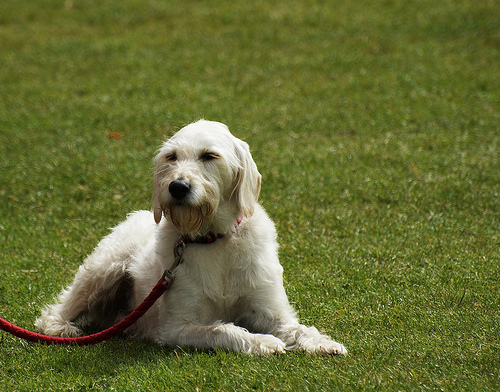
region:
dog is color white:
[22, 105, 349, 367]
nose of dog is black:
[164, 172, 191, 204]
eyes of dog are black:
[160, 144, 221, 165]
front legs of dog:
[172, 305, 357, 369]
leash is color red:
[1, 227, 202, 355]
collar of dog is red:
[161, 216, 251, 250]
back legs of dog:
[31, 257, 123, 342]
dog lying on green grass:
[28, 103, 353, 380]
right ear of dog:
[228, 135, 270, 222]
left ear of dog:
[148, 152, 168, 225]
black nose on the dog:
[167, 180, 191, 200]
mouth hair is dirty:
[162, 204, 209, 227]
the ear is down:
[233, 144, 259, 214]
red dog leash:
[0, 278, 171, 345]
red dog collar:
[185, 213, 244, 245]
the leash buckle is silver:
[161, 238, 185, 279]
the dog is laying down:
[37, 117, 347, 357]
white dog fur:
[108, 219, 153, 266]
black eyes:
[160, 151, 217, 160]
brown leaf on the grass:
[107, 131, 119, 138]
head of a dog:
[124, 83, 275, 247]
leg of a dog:
[152, 308, 263, 373]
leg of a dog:
[249, 295, 330, 351]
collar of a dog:
[157, 205, 254, 268]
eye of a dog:
[163, 141, 187, 175]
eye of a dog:
[189, 131, 230, 173]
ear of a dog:
[141, 175, 191, 231]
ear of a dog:
[230, 129, 292, 216]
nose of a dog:
[166, 171, 200, 192]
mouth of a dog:
[152, 198, 224, 229]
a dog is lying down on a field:
[23, 101, 373, 380]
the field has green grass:
[6, 9, 491, 386]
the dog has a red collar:
[167, 209, 251, 249]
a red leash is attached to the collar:
[1, 238, 199, 356]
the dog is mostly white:
[33, 116, 348, 359]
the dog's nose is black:
[166, 177, 193, 201]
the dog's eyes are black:
[155, 150, 226, 161]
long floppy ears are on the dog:
[141, 131, 266, 231]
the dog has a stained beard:
[152, 198, 220, 237]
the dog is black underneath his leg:
[53, 261, 194, 358]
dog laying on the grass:
[23, 111, 362, 375]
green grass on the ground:
[1, 0, 499, 388]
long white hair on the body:
[32, 112, 352, 367]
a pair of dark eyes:
[159, 145, 226, 165]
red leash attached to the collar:
[0, 237, 201, 342]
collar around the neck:
[173, 208, 258, 246]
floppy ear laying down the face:
[231, 133, 277, 223]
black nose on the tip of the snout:
[167, 177, 199, 201]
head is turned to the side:
[142, 120, 274, 235]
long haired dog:
[31, 105, 377, 375]